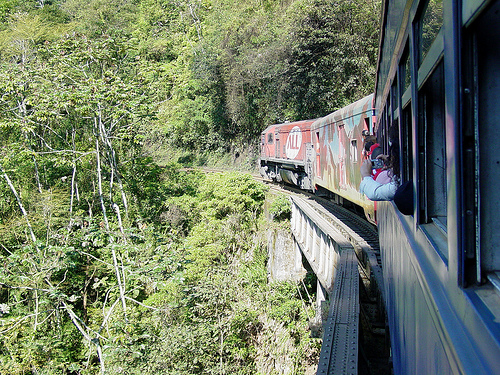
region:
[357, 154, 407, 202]
person taking picture from train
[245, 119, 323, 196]
red train engine in front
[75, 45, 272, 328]
foliage growing around track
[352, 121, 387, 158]
people leaning out train windows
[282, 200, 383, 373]
railroad bridge with train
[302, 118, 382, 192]
colorful train car behind engine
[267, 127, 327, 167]
train with ALL logo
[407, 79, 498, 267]
open windows on train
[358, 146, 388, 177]
person holding camera phone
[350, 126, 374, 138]
person wearing baseball cap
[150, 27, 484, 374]
a train on a bridge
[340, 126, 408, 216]
items hanging outside of the train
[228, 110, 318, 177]
the engine is red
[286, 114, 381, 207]
thi car is colorful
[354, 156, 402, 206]
this person's arm is outside of the train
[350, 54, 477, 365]
a blue train car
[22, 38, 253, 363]
green leaves on a tree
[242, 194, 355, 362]
a bridge with tracks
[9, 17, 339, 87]
a lot of green trees in the environment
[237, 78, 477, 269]
three train cars on the track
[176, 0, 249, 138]
tall leafy tree branch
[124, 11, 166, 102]
tall leafy tree branch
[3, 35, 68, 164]
tall leafy tree branch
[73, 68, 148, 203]
tall leafy tree branch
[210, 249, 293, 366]
tall leafy tree branch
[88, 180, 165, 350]
tall leafy tree branch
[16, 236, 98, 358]
tall leafy tree branch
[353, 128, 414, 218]
persons hand outside on train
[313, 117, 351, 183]
painting on side train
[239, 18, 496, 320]
passenger train on tracks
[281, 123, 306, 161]
a white circle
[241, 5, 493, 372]
an old train on a railroad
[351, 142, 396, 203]
a person taking a picture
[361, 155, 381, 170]
person wears a camera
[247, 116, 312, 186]
car of trai is red and white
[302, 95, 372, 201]
car of train has brown designs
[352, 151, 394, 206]
a long sleeve color blue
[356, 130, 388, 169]
the head of a person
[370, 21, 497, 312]
windows of a train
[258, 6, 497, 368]
a train over a bridge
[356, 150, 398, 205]
hands holding a camera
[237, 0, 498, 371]
a train passing a bridge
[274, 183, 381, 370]
a fence on bridge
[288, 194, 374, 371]
fence is made of wood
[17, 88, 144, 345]
branches on a tree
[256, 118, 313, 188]
car of train is red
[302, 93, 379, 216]
car of train has brown spots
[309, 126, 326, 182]
a door on train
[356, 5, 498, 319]
the windows of train